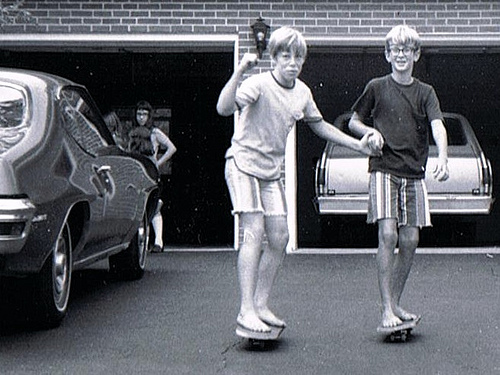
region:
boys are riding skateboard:
[179, 7, 441, 353]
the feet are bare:
[221, 280, 460, 360]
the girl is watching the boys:
[115, 89, 205, 272]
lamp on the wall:
[237, 5, 273, 68]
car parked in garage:
[308, 77, 498, 233]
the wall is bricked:
[133, 12, 419, 80]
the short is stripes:
[346, 155, 461, 253]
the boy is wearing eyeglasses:
[377, 30, 416, 74]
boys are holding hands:
[254, 9, 486, 219]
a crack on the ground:
[194, 330, 263, 370]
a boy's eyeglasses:
[390, 43, 420, 55]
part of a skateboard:
[375, 310, 423, 343]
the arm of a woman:
[152, 130, 177, 166]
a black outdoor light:
[245, 18, 267, 54]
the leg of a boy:
[391, 190, 418, 301]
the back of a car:
[315, 108, 495, 233]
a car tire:
[36, 215, 76, 325]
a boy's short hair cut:
[380, 22, 421, 53]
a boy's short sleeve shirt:
[225, 71, 320, 179]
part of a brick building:
[2, 0, 498, 38]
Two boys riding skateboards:
[202, 18, 461, 352]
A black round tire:
[23, 218, 80, 334]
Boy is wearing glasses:
[383, 38, 421, 63]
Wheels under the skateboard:
[381, 326, 413, 346]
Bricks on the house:
[69, 2, 154, 31]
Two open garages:
[6, 21, 497, 264]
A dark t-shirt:
[355, 69, 453, 186]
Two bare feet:
[228, 296, 290, 338]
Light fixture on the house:
[242, 11, 277, 60]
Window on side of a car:
[51, 80, 122, 161]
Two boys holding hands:
[216, 28, 491, 363]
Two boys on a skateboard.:
[211, 31, 492, 373]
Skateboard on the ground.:
[199, 284, 340, 364]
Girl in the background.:
[107, 84, 206, 269]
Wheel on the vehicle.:
[48, 215, 88, 347]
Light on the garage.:
[231, 17, 287, 55]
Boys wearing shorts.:
[210, 20, 455, 254]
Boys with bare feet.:
[222, 247, 420, 349]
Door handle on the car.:
[88, 127, 140, 194]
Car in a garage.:
[320, 82, 474, 254]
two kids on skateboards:
[196, 11, 431, 315]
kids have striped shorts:
[223, 143, 427, 284]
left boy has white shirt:
[252, 78, 309, 185]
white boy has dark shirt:
[359, 81, 443, 185]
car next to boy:
[6, 131, 136, 322]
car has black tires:
[12, 168, 89, 345]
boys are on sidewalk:
[88, 240, 422, 347]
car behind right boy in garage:
[304, 101, 484, 243]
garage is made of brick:
[250, 11, 431, 53]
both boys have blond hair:
[257, 29, 457, 99]